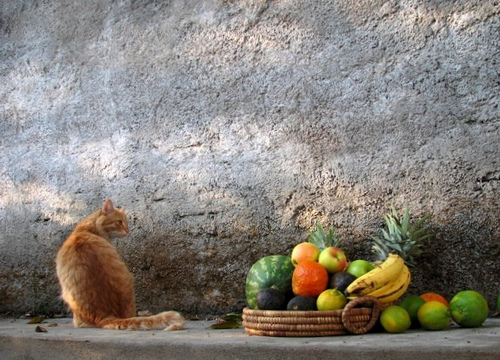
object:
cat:
[55, 198, 185, 331]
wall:
[2, 1, 500, 317]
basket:
[241, 298, 382, 338]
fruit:
[244, 203, 488, 331]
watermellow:
[243, 253, 294, 310]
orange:
[291, 262, 327, 297]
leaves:
[400, 203, 411, 237]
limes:
[450, 290, 488, 328]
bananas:
[345, 253, 405, 297]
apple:
[318, 246, 348, 271]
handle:
[340, 294, 380, 335]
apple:
[290, 242, 319, 266]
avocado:
[254, 289, 288, 311]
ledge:
[1, 315, 500, 360]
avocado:
[285, 295, 318, 311]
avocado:
[330, 270, 355, 291]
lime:
[416, 300, 449, 327]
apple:
[346, 259, 371, 277]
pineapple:
[390, 269, 451, 333]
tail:
[103, 309, 188, 333]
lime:
[400, 294, 426, 327]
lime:
[380, 304, 411, 333]